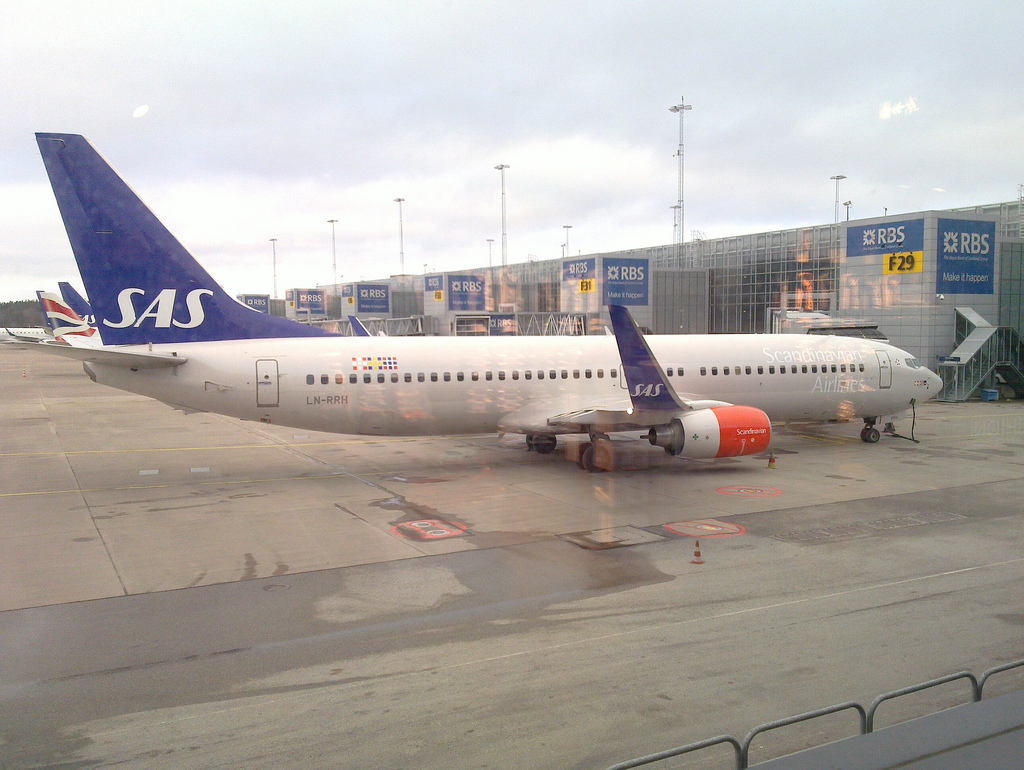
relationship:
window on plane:
[301, 368, 312, 392] [34, 120, 974, 531]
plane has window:
[12, 128, 1019, 616] [762, 342, 879, 399]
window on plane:
[346, 339, 382, 369] [32, 121, 957, 476]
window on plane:
[430, 372, 438, 381] [32, 121, 957, 476]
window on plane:
[434, 343, 455, 394] [32, 121, 957, 476]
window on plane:
[403, 355, 422, 391] [32, 121, 957, 476]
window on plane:
[440, 348, 457, 381] [32, 121, 957, 476]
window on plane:
[488, 367, 507, 390] [32, 121, 957, 476]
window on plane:
[545, 353, 568, 386] [32, 121, 957, 476]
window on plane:
[476, 356, 516, 392] [43, 135, 981, 488]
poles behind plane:
[484, 155, 495, 286] [43, 134, 935, 460]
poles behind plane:
[672, 90, 695, 283] [43, 134, 935, 460]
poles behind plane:
[392, 188, 400, 291] [43, 134, 935, 460]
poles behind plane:
[265, 225, 276, 299] [43, 134, 935, 460]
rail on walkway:
[650, 644, 994, 765] [724, 668, 1022, 767]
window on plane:
[859, 365, 867, 372] [32, 121, 957, 476]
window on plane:
[483, 364, 500, 385] [32, 121, 957, 476]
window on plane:
[467, 365, 483, 381] [32, 121, 957, 476]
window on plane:
[512, 361, 530, 379] [0, 76, 946, 504]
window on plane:
[525, 370, 534, 379] [32, 121, 957, 476]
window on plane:
[465, 365, 541, 400] [61, 184, 936, 476]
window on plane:
[507, 364, 524, 385] [32, 121, 957, 476]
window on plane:
[401, 370, 415, 390] [32, 121, 957, 476]